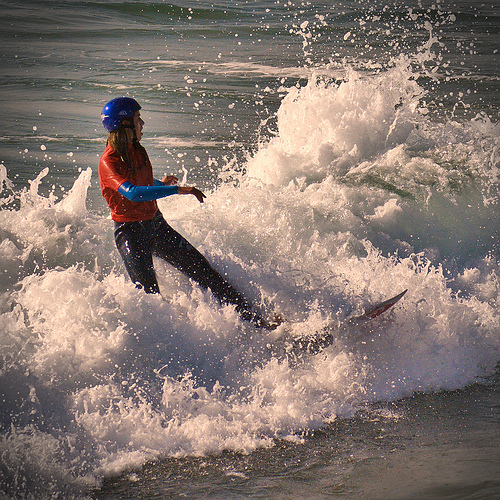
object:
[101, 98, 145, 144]
head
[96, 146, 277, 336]
wetsuit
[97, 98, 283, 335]
person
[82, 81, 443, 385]
woman surfing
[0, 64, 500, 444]
white water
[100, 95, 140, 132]
blue safety helmet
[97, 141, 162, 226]
red shirt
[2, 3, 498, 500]
green ocean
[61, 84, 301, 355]
woman standing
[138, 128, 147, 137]
mouth open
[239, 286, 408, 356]
surfboard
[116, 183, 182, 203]
blue underneath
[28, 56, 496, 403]
water splashing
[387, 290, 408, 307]
tip of surfboard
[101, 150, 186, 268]
orange and black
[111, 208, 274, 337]
dark wetsuit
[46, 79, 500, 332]
white water splash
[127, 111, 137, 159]
black straps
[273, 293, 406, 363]
red water ski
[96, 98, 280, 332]
water skier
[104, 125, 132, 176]
brown hair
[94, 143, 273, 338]
surfer wears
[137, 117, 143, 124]
he nose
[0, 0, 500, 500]
drops of water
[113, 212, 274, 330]
wet pants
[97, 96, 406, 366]
person surfing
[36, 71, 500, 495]
surfing in ocean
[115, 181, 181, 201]
wearing blue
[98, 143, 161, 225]
orange shirts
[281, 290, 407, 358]
board used by surfer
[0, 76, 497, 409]
waves in ocean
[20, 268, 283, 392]
white and gray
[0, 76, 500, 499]
gray waves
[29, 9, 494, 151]
gray waves in ocean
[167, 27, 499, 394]
white and gray waves